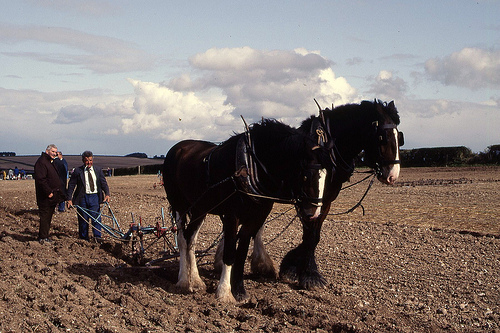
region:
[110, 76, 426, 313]
a team of horses plowing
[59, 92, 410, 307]
an overly dressed farmer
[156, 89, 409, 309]
clydesdales hard at work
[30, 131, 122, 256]
someone watching someone plow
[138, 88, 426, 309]
two horses with white face markings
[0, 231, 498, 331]
plowing rocky soil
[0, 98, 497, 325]
a blue metal plow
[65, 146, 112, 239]
a tie, white shirt, suit coat and jeans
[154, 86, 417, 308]
horses with blinders for focus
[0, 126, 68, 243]
gray bearded man with hand in pocket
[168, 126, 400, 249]
two horse are seen.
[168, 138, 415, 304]
horse are black and white in color.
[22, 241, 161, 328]
mud is brown in color.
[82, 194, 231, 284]
horse is ploughing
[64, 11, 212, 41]
sky is blue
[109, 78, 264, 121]
clouds are white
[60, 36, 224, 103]
sky with clouds.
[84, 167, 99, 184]
man is wearing tie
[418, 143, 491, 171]
trees are found at the back.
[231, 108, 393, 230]
belt are black in color.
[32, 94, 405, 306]
Men working with horses to plow field.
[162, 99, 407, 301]
Two work horses.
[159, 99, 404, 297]
Two brown and white horses.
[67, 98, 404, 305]
Two brown and white horses hitched to a plow.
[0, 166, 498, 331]
Field.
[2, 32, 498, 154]
Cloudy sky.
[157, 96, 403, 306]
Horses wearing yokes.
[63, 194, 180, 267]
Blue hand plow.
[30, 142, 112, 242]
Men standing in field.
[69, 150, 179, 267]
Man working with hand plow.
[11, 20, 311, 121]
A cloudy sky.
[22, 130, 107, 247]
A group of middle aged men.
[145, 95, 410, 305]
Two large brown horses.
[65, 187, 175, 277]
A plow.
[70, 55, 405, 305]
The man and the horses are plowing the field.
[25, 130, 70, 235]
The man is watching the other man and the horses.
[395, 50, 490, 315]
An empty field.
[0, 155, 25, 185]
A small group of people.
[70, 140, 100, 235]
The man is chewing on something.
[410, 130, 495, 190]
A forest at the far end of the field.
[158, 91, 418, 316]
A pair of Clydesdale horses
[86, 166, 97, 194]
A tie on a man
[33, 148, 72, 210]
A black jacket on a man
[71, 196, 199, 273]
A plow behind the horses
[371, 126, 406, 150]
Pair of blinders on the horse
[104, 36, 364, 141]
Fluffy white clouds in the sky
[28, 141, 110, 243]
Three men behind the horses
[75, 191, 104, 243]
Blue jeans on a man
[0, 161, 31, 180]
A group of people in the background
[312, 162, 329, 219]
A stripe of white on the horse's face